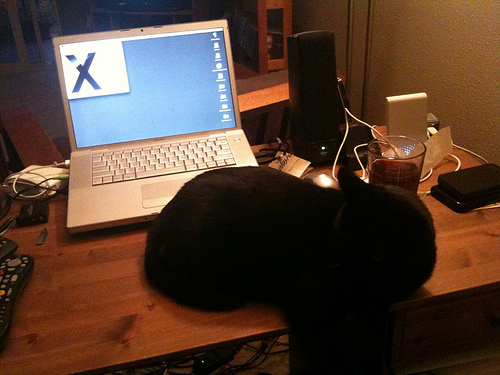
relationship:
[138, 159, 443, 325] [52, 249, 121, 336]
cat laying on top of desk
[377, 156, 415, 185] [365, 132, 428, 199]
liquid in a glass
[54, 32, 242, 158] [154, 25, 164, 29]
computer has speaker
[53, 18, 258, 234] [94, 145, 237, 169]
computer has keyboard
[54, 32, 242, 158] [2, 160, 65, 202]
computer has router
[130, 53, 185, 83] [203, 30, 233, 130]
screen has icons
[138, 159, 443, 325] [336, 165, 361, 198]
cat has ear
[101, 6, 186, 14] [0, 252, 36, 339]
tv has remote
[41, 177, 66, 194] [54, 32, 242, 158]
wires plugged into computer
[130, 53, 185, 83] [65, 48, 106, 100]
screen has x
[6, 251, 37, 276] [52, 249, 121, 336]
remote on top of desk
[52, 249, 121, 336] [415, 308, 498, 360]
desk has drawers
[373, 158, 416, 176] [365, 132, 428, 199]
half full glass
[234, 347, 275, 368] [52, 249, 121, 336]
cords under desk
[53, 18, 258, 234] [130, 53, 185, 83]
computer has screen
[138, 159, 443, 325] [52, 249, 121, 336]
cat on top of desk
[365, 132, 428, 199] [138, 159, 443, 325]
drink behind cat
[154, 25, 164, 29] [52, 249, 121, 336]
speaker on top of desk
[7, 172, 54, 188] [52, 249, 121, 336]
phone on top of desk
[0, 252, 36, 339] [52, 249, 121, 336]
remote on top of desk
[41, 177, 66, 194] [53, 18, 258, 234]
wires in computer